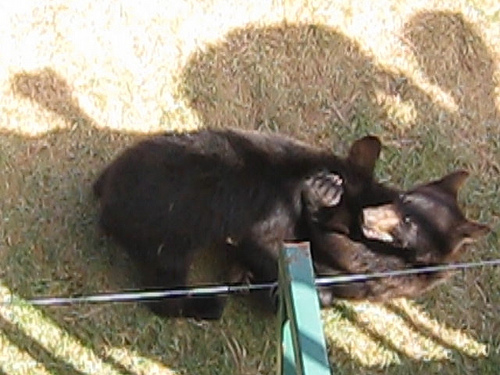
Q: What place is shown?
A: It is a zoo.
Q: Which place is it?
A: It is a zoo.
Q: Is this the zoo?
A: Yes, it is the zoo.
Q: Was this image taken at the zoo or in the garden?
A: It was taken at the zoo.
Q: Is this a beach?
A: No, it is a zoo.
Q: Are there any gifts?
A: No, there are no gifts.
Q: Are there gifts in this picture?
A: No, there are no gifts.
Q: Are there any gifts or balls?
A: No, there are no gifts or balls.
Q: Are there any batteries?
A: No, there are no batteries.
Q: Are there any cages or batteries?
A: No, there are no batteries or cages.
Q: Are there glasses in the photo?
A: No, there are no glasses.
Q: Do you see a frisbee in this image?
A: No, there are no frisbees.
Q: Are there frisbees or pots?
A: No, there are no frisbees or pots.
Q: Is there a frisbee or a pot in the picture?
A: No, there are no frisbees or pots.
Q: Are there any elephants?
A: No, there are no elephants.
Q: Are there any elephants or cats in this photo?
A: No, there are no elephants or cats.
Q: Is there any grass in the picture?
A: Yes, there is grass.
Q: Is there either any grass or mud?
A: Yes, there is grass.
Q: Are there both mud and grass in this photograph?
A: No, there is grass but no mud.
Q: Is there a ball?
A: No, there are no balls.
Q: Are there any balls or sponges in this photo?
A: No, there are no balls or sponges.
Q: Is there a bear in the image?
A: Yes, there is a bear.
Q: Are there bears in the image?
A: Yes, there is a bear.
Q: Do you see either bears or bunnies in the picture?
A: Yes, there is a bear.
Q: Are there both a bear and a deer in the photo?
A: No, there is a bear but no deer.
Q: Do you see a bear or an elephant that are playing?
A: Yes, the bear is playing.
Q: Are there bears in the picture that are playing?
A: Yes, there is a bear that is playing.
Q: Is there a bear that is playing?
A: Yes, there is a bear that is playing.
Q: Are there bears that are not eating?
A: Yes, there is a bear that is playing.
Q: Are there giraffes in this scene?
A: No, there are no giraffes.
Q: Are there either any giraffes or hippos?
A: No, there are no giraffes or hippos.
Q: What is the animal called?
A: The animal is a bear.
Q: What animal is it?
A: The animal is a bear.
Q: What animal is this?
A: This is a bear.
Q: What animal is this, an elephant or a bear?
A: This is a bear.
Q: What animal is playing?
A: The animal is a bear.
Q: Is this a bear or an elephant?
A: This is a bear.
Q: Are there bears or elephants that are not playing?
A: No, there is a bear but it is playing.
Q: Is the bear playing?
A: Yes, the bear is playing.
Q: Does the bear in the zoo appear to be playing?
A: Yes, the bear is playing.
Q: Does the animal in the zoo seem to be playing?
A: Yes, the bear is playing.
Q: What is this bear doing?
A: The bear is playing.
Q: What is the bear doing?
A: The bear is playing.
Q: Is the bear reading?
A: No, the bear is playing.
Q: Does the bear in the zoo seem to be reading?
A: No, the bear is playing.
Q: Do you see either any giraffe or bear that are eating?
A: No, there is a bear but it is playing.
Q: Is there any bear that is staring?
A: No, there is a bear but it is playing.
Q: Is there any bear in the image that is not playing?
A: No, there is a bear but it is playing.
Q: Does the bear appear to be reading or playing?
A: The bear is playing.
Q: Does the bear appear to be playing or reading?
A: The bear is playing.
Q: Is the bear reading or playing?
A: The bear is playing.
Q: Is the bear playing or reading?
A: The bear is playing.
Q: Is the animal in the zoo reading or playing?
A: The bear is playing.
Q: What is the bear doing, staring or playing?
A: The bear is playing.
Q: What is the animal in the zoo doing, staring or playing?
A: The bear is playing.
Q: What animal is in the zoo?
A: The bear is in the zoo.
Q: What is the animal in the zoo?
A: The animal is a bear.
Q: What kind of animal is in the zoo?
A: The animal is a bear.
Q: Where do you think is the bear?
A: The bear is in the zoo.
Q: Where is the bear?
A: The bear is in the zoo.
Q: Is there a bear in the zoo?
A: Yes, there is a bear in the zoo.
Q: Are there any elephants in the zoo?
A: No, there is a bear in the zoo.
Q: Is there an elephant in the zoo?
A: No, there is a bear in the zoo.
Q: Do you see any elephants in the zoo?
A: No, there is a bear in the zoo.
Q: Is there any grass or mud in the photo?
A: Yes, there is grass.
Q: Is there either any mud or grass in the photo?
A: Yes, there is grass.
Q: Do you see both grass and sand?
A: No, there is grass but no sand.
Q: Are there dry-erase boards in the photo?
A: No, there are no dry-erase boards.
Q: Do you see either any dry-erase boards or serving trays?
A: No, there are no dry-erase boards or serving trays.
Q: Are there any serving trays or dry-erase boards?
A: No, there are no dry-erase boards or serving trays.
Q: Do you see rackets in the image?
A: No, there are no rackets.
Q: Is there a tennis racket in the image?
A: No, there are no rackets.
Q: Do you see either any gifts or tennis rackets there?
A: No, there are no tennis rackets or gifts.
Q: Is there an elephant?
A: No, there are no elephants.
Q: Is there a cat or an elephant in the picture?
A: No, there are no elephants or cats.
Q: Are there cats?
A: No, there are no cats.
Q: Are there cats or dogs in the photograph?
A: No, there are no cats or dogs.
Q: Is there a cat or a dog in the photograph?
A: No, there are no cats or dogs.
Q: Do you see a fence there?
A: Yes, there is a fence.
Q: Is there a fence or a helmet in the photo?
A: Yes, there is a fence.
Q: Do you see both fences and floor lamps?
A: No, there is a fence but no floor lamps.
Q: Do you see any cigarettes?
A: No, there are no cigarettes.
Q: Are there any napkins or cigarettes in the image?
A: No, there are no cigarettes or napkins.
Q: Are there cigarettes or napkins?
A: No, there are no cigarettes or napkins.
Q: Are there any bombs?
A: No, there are no bombs.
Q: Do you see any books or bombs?
A: No, there are no bombs or books.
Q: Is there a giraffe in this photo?
A: No, there are no giraffes.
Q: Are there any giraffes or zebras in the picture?
A: No, there are no giraffes or zebras.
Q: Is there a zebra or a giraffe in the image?
A: No, there are no giraffes or zebras.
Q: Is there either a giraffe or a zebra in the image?
A: No, there are no giraffes or zebras.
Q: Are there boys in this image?
A: No, there are no boys.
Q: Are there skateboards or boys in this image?
A: No, there are no boys or skateboards.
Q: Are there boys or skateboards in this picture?
A: No, there are no boys or skateboards.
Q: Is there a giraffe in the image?
A: No, there are no giraffes.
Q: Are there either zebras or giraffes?
A: No, there are no giraffes or zebras.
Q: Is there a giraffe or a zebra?
A: No, there are no giraffes or zebras.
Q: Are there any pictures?
A: No, there are no pictures.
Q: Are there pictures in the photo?
A: No, there are no pictures.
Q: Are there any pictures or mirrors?
A: No, there are no pictures or mirrors.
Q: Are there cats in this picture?
A: No, there are no cats.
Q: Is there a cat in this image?
A: No, there are no cats.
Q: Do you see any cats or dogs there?
A: No, there are no cats or dogs.